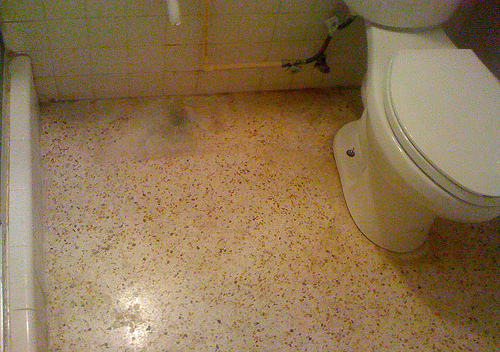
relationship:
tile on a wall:
[170, 45, 205, 82] [7, 6, 347, 110]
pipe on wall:
[208, 58, 308, 73] [223, 10, 299, 67]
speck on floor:
[218, 247, 228, 255] [37, 80, 493, 347]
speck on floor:
[217, 245, 226, 254] [37, 80, 493, 347]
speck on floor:
[167, 230, 177, 236] [37, 80, 493, 347]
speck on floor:
[139, 217, 149, 228] [37, 80, 493, 347]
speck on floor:
[253, 221, 260, 231] [37, 80, 493, 347]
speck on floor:
[129, 240, 137, 249] [37, 80, 493, 347]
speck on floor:
[88, 248, 98, 258] [37, 80, 493, 347]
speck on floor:
[145, 325, 155, 333] [37, 80, 493, 347]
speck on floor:
[203, 338, 213, 348] [49, 79, 420, 350]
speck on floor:
[215, 318, 221, 326] [37, 80, 493, 347]